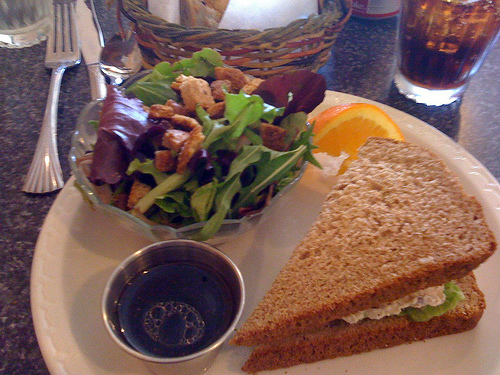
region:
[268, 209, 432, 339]
sandwich sliced in half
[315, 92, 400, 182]
orange wedge on plate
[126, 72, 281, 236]
small salad in bowl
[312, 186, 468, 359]
sandwich with brown bread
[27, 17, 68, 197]
silver fork on table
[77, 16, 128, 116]
silver knife on table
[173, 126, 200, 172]
crouton on a salad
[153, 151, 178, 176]
crouton on a salad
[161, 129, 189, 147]
crouton on a salad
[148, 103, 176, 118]
crouton on a salad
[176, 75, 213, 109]
crouton on a salad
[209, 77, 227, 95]
crouton on a salad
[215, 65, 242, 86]
crouton on a salad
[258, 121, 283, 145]
crouton on a salad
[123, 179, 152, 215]
crouton on a salad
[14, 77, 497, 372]
there is a plate of food on the table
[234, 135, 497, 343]
The tuna sandwich is on the plate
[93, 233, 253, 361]
The sauce in the bowl in dark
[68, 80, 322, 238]
the salad for the sandwich is on the plate as well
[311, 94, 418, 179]
the orange slice is on the plate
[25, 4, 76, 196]
The fork is on the left side of the plate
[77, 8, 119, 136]
the knife is next to the fork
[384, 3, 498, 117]
the glass is filled with a dark liquid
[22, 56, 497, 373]
The plate the food is on is white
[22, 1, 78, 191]
the decorative silver fork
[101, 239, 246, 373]
the small silver container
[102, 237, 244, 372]
the liquid in the silver container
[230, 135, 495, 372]
the half of a sandwich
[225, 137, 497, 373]
the wheat bread on the sandwich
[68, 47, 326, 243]
the salad in the bowl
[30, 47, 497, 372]
the sandwich and salad on the white plate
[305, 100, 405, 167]
the wedge of an orange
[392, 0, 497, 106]
the brown liquid in the clear glass cup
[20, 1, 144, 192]
the silver fork, knife and spoon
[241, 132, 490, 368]
Half sandwich on wheat bread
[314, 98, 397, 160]
twisted slice of orange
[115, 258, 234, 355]
a side of balsamic salad dressing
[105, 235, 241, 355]
stainless steel condiment container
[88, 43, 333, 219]
mixed greens salad with red arugula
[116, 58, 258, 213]
croutons on a mixed greens salad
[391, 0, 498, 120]
a soft drink over ice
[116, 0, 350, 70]
a basket of bread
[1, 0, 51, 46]
bottom of glass for ice water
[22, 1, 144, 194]
stainless flatware on speckled table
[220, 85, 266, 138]
lettuce on a bowl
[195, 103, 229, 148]
lettuce on a bowl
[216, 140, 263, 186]
lettuce on a bowl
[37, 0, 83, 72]
Prongs of a fork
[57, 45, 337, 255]
A bowl of salad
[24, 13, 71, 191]
The knife to the left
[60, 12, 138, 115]
A knife to the left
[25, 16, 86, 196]
The fork to the left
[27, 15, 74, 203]
A silver fork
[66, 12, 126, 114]
The silver knife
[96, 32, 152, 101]
The silver spoon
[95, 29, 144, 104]
A silver spoon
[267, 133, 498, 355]
The sandwich on the plate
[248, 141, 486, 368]
A sandwich on the plate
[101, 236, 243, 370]
stainless steel cup of dressing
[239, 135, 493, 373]
sandwich cut in a triangle